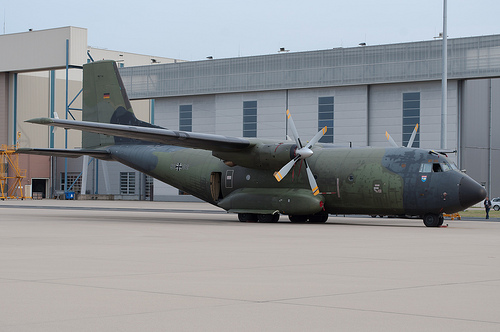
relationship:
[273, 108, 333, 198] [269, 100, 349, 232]
stripes on propeller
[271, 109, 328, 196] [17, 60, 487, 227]
propeller on airplane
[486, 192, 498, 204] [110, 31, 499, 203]
car parked on side of building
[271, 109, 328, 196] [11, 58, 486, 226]
propeller of plane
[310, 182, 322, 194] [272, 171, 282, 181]
stripes on tip of stripes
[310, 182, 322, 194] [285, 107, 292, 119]
stripes on tip of stripes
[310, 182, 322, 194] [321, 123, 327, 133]
stripes on tip of stripes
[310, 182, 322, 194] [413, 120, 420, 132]
stripes on tip of stripes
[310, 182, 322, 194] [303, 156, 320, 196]
stripes on tip of blade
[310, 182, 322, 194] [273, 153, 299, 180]
stripes on tip of blade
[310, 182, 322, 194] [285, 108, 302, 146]
stripes on tip of blade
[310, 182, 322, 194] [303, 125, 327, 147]
stripes on tip of blade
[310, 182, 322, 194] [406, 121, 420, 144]
stripes on tip of blade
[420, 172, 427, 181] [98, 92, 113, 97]
flag painted under flag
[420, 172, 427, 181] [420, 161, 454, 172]
flag painted under window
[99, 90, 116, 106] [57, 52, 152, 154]
flag painted on tail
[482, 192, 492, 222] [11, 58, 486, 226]
person standing next to plane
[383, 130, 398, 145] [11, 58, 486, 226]
propeller on plane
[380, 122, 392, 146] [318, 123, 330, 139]
stripes on stripes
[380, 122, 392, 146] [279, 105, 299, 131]
stripes on stripes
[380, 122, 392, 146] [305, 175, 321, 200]
stripes on stripes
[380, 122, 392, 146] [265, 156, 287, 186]
stripes on stripes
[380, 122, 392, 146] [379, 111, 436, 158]
stripes on propeller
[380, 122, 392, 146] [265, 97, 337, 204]
stripes on propeller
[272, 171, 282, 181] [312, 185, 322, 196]
stripes on stripes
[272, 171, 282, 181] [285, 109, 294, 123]
stripes on stripes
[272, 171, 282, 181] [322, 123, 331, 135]
stripes on stripes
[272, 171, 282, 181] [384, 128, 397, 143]
stripes on stripes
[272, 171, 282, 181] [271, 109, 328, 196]
stripes on propeller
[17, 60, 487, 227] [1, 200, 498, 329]
airplane on tarmac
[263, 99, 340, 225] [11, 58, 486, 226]
propeller on front of plane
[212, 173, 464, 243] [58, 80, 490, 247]
tires on bottom of plane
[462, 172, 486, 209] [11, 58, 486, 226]
nose on front of plane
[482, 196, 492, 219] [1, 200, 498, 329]
person walking on tarmac